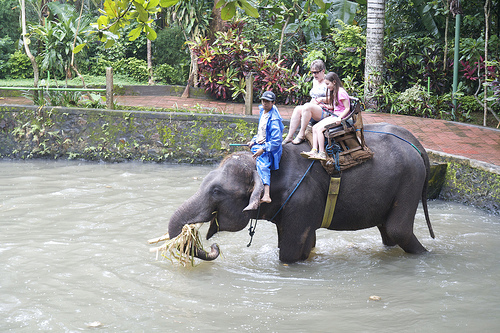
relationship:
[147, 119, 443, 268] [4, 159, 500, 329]
elephant in water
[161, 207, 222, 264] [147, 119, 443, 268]
trunk of elephant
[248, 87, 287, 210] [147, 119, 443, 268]
man on elephant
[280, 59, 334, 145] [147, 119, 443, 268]
tourists on elephant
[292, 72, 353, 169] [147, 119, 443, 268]
girl on elephant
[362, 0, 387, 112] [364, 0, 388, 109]
palm tree of palm tree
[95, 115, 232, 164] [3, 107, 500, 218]
moss on wall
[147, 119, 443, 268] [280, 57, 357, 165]
elephant carries tourists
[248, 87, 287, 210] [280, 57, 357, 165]
tour guide with tourists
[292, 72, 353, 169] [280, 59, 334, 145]
girl and tourists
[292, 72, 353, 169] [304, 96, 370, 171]
girl in seat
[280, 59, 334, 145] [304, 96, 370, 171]
tourists in seat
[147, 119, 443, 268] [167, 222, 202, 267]
elephant snacks on leaves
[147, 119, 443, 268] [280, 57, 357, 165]
elephant carrying people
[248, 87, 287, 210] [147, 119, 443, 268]
man rides animal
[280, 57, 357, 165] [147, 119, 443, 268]
people ride on mammal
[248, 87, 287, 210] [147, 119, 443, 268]
person riding elephant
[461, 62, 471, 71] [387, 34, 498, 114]
leaf on bush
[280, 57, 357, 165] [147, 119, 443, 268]
tourists riding elephant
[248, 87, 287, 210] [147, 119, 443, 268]
man directing elephant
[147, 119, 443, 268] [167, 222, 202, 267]
elephant pulling grasses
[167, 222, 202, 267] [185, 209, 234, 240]
grasses into mouth